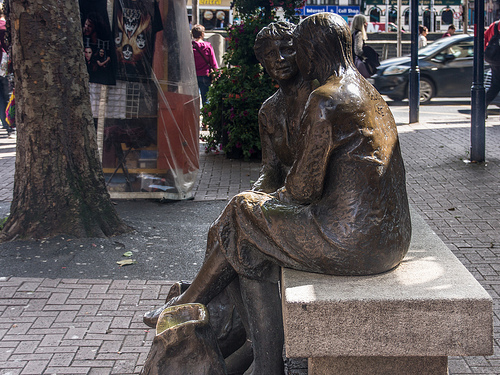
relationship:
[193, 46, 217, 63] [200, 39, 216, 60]
strap around shoulder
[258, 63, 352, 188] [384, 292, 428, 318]
statues on bench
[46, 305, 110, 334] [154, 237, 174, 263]
bricks on ground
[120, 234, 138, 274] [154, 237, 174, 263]
leaves on ground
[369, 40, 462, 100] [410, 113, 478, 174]
car on path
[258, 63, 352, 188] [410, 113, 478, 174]
statues on path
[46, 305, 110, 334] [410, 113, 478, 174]
bricks on path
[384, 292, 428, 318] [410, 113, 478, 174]
bench on path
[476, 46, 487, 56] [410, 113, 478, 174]
post in path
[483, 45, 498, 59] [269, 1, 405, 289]
backpack on man